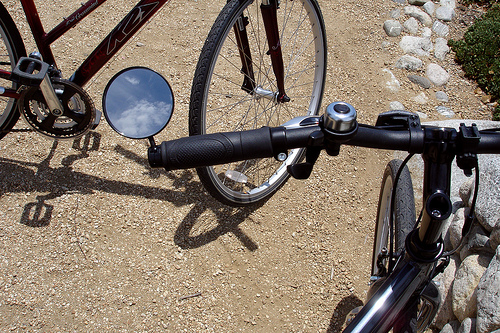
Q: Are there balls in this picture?
A: No, there are no balls.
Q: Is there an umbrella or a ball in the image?
A: No, there are no balls or umbrellas.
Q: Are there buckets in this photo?
A: No, there are no buckets.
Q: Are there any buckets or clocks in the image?
A: No, there are no buckets or clocks.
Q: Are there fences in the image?
A: No, there are no fences.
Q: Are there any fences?
A: No, there are no fences.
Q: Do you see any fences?
A: No, there are no fences.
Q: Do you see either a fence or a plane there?
A: No, there are no fences or airplanes.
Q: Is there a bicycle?
A: Yes, there is a bicycle.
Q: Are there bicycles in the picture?
A: Yes, there is a bicycle.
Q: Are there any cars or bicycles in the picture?
A: Yes, there is a bicycle.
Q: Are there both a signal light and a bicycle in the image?
A: No, there is a bicycle but no traffic lights.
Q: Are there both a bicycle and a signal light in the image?
A: No, there is a bicycle but no traffic lights.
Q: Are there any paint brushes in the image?
A: No, there are no paint brushes.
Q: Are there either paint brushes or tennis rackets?
A: No, there are no paint brushes or tennis rackets.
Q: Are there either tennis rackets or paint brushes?
A: No, there are no paint brushes or tennis rackets.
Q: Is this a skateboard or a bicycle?
A: This is a bicycle.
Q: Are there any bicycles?
A: Yes, there is a bicycle.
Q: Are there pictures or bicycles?
A: Yes, there is a bicycle.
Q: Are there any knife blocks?
A: No, there are no knife blocks.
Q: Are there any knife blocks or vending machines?
A: No, there are no knife blocks or vending machines.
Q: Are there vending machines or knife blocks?
A: No, there are no knife blocks or vending machines.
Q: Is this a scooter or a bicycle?
A: This is a bicycle.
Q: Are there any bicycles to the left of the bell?
A: Yes, there is a bicycle to the left of the bell.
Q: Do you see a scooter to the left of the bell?
A: No, there is a bicycle to the left of the bell.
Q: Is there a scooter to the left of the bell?
A: No, there is a bicycle to the left of the bell.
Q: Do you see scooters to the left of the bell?
A: No, there is a bicycle to the left of the bell.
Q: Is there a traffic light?
A: No, there are no traffic lights.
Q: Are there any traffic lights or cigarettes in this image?
A: No, there are no traffic lights or cigarettes.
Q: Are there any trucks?
A: No, there are no trucks.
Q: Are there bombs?
A: No, there are no bombs.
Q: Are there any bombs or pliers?
A: No, there are no bombs or pliers.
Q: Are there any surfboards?
A: No, there are no surfboards.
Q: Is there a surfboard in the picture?
A: No, there are no surfboards.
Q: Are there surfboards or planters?
A: No, there are no surfboards or planters.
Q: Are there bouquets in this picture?
A: No, there are no bouquets.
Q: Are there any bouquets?
A: No, there are no bouquets.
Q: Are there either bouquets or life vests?
A: No, there are no bouquets or life vests.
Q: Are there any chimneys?
A: No, there are no chimneys.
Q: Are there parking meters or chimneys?
A: No, there are no chimneys or parking meters.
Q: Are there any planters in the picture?
A: No, there are no planters.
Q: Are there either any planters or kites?
A: No, there are no planters or kites.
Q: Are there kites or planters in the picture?
A: No, there are no planters or kites.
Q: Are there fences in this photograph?
A: No, there are no fences.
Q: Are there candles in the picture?
A: No, there are no candles.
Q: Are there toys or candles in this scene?
A: No, there are no candles or toys.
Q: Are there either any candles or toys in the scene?
A: No, there are no candles or toys.